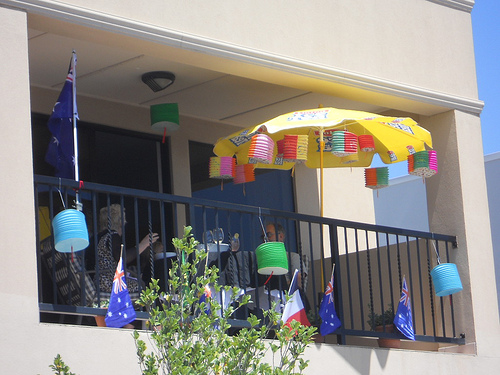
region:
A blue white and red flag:
[385, 278, 437, 342]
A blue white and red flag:
[318, 257, 358, 344]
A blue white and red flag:
[272, 259, 314, 335]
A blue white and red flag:
[99, 253, 139, 326]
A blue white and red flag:
[42, 38, 109, 170]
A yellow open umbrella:
[237, 95, 436, 175]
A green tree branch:
[240, 298, 326, 360]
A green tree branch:
[192, 268, 227, 358]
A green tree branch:
[165, 239, 210, 353]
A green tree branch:
[126, 327, 166, 372]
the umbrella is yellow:
[212, 107, 434, 172]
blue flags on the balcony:
[89, 245, 418, 343]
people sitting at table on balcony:
[90, 203, 297, 332]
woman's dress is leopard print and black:
[89, 231, 145, 296]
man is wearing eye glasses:
[258, 219, 287, 242]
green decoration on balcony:
[250, 235, 293, 277]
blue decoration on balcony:
[426, 249, 463, 301]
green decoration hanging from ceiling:
[145, 94, 183, 146]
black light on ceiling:
[133, 62, 178, 96]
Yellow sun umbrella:
[210, 103, 433, 333]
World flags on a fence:
[103, 242, 425, 347]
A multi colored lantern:
[241, 126, 282, 171]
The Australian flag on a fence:
[106, 245, 137, 328]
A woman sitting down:
[94, 201, 155, 303]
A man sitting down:
[256, 223, 305, 295]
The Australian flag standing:
[43, 37, 94, 200]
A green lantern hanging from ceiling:
[148, 99, 185, 139]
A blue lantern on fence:
[430, 253, 465, 307]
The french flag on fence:
[266, 267, 316, 343]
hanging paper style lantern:
[241, 129, 279, 168]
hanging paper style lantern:
[208, 155, 236, 177]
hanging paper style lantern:
[231, 162, 255, 186]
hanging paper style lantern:
[282, 133, 305, 161]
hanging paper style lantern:
[327, 130, 356, 161]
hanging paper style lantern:
[356, 133, 373, 151]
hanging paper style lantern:
[363, 168, 390, 189]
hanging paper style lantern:
[409, 146, 438, 175]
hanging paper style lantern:
[433, 260, 464, 295]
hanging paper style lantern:
[253, 241, 289, 277]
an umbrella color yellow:
[198, 96, 448, 338]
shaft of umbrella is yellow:
[307, 125, 332, 285]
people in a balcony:
[21, 6, 476, 355]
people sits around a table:
[89, 180, 311, 331]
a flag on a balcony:
[39, 45, 99, 211]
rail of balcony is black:
[35, 178, 473, 348]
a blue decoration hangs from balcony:
[418, 225, 465, 303]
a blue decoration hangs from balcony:
[43, 176, 94, 277]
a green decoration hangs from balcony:
[246, 200, 298, 290]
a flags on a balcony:
[100, 240, 138, 334]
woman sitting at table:
[92, 179, 181, 330]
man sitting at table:
[208, 211, 312, 324]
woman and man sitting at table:
[43, 170, 321, 340]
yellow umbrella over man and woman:
[97, 102, 441, 328]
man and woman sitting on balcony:
[63, 182, 318, 348]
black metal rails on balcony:
[314, 207, 470, 372]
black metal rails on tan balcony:
[331, 169, 486, 366]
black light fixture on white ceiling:
[136, 66, 183, 99]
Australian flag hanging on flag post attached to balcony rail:
[41, 45, 84, 187]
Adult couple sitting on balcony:
[93, 201, 311, 313]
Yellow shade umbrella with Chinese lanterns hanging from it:
[208, 103, 439, 319]